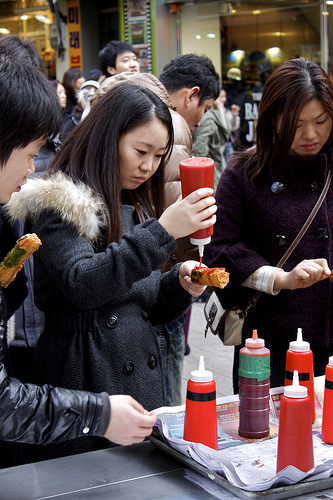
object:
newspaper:
[147, 374, 333, 493]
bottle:
[276, 374, 315, 479]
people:
[212, 87, 240, 176]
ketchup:
[182, 355, 219, 459]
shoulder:
[23, 184, 101, 226]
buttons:
[82, 426, 90, 434]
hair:
[228, 57, 332, 188]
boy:
[89, 53, 221, 406]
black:
[170, 60, 204, 81]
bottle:
[236, 327, 270, 439]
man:
[75, 39, 141, 125]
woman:
[60, 79, 102, 145]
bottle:
[181, 355, 219, 453]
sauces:
[237, 329, 272, 440]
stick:
[0, 232, 42, 288]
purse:
[201, 156, 333, 347]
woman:
[201, 55, 332, 397]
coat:
[1, 172, 201, 445]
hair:
[0, 35, 62, 170]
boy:
[0, 29, 158, 450]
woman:
[31, 83, 218, 462]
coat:
[202, 142, 333, 382]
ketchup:
[191, 257, 226, 275]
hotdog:
[191, 267, 230, 289]